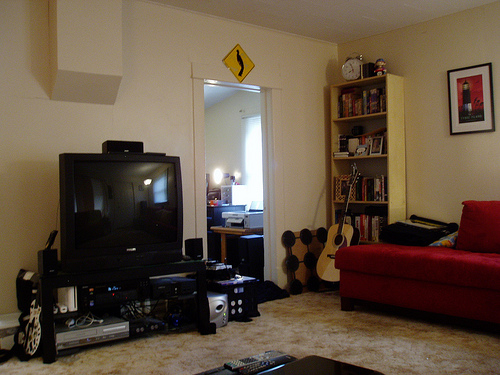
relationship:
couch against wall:
[336, 201, 499, 331] [409, 4, 448, 208]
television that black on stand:
[56, 154, 183, 268] [41, 263, 209, 361]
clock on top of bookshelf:
[339, 58, 363, 82] [327, 54, 408, 90]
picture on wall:
[445, 62, 496, 136] [407, 27, 500, 201]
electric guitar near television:
[1, 228, 60, 367] [56, 154, 183, 268]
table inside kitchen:
[210, 226, 265, 261] [207, 83, 264, 259]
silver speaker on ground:
[208, 291, 231, 327] [3, 309, 500, 373]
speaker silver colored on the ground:
[208, 291, 231, 327] [3, 309, 500, 373]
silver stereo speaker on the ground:
[208, 291, 231, 327] [3, 309, 500, 373]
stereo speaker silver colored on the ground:
[208, 291, 231, 327] [3, 309, 500, 373]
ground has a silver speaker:
[3, 309, 500, 373] [208, 291, 231, 327]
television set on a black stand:
[56, 154, 183, 268] [41, 263, 209, 361]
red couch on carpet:
[336, 201, 499, 331] [3, 309, 500, 373]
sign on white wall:
[222, 40, 256, 85] [0, 2, 491, 313]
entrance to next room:
[203, 44, 275, 259] [207, 83, 264, 259]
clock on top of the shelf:
[339, 58, 363, 82] [327, 54, 408, 90]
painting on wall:
[445, 62, 496, 136] [407, 27, 500, 201]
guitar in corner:
[315, 168, 360, 284] [269, 29, 403, 296]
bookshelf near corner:
[327, 76, 408, 243] [0, 1, 498, 198]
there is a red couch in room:
[336, 201, 499, 331] [3, 4, 497, 371]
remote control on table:
[215, 348, 296, 374] [188, 348, 385, 374]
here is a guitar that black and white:
[1, 228, 60, 367] [14, 287, 43, 365]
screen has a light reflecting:
[72, 162, 176, 242] [143, 173, 153, 190]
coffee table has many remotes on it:
[188, 348, 385, 374] [215, 348, 296, 374]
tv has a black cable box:
[56, 154, 183, 268] [93, 283, 142, 308]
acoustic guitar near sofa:
[315, 168, 360, 284] [336, 201, 499, 331]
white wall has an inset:
[2, 2, 203, 141] [50, 0, 123, 105]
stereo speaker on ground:
[208, 291, 231, 327] [154, 332, 335, 361]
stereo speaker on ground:
[208, 291, 231, 327] [182, 327, 343, 364]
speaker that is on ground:
[208, 291, 231, 327] [172, 327, 378, 373]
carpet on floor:
[2, 288, 484, 373] [3, 309, 500, 373]